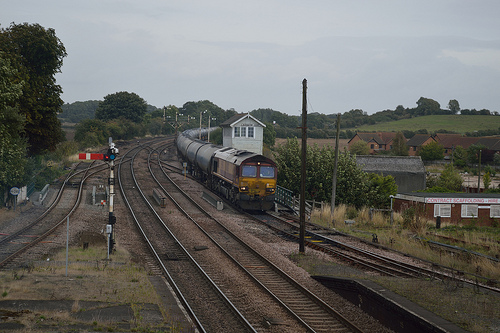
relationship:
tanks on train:
[172, 125, 222, 182] [177, 125, 278, 212]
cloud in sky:
[27, 3, 499, 117] [43, 16, 465, 118]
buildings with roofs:
[338, 124, 498, 171] [337, 122, 499, 155]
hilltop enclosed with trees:
[304, 99, 496, 144] [444, 95, 461, 115]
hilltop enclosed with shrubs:
[304, 99, 496, 144] [367, 105, 400, 127]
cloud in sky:
[57, 25, 499, 117] [2, 2, 497, 114]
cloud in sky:
[27, 3, 499, 117] [2, 2, 497, 114]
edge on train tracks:
[46, 127, 152, 203] [1, 134, 498, 331]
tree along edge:
[1, 27, 35, 205] [46, 127, 152, 203]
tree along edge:
[2, 20, 66, 160] [46, 127, 152, 203]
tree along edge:
[77, 132, 98, 149] [46, 127, 152, 203]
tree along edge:
[97, 90, 147, 124] [46, 127, 152, 203]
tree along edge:
[117, 117, 135, 138] [46, 127, 152, 203]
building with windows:
[217, 107, 269, 159] [233, 126, 257, 138]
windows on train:
[433, 204, 498, 221] [177, 125, 278, 212]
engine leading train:
[224, 153, 272, 213] [173, 113, 209, 178]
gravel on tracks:
[196, 224, 249, 276] [140, 219, 313, 319]